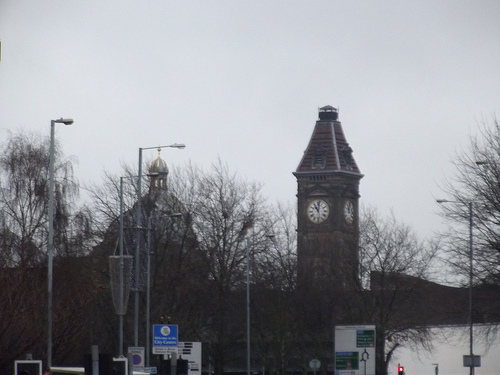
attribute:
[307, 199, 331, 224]
clock — white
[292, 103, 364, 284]
tower — stone, brick, large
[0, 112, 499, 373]
trees — bare, tall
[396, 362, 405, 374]
traffic light — red, lit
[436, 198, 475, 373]
lamp post — tall, gray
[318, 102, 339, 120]
roof — round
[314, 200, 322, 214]
hands — black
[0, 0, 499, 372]
sky — grey, overcast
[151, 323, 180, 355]
sign — blue, white